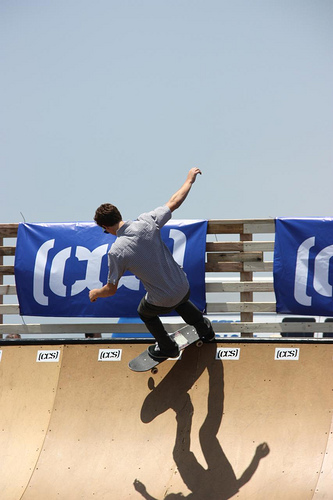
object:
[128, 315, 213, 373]
skateboard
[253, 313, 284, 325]
snow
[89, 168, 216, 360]
man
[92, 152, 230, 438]
tricks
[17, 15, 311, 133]
sky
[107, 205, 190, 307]
shirt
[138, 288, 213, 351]
jeans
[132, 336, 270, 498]
shadow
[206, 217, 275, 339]
fence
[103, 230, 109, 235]
sunglasses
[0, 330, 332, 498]
halfpipe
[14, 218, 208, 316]
banner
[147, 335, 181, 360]
shoes